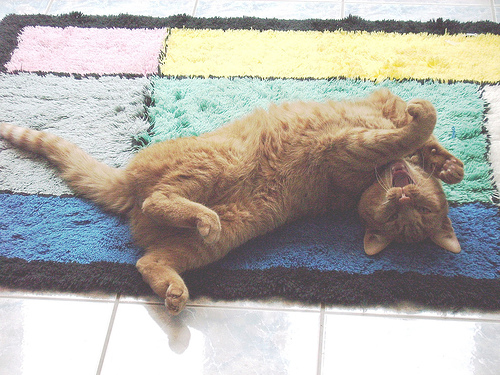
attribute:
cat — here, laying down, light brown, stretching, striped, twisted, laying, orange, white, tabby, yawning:
[0, 91, 460, 320]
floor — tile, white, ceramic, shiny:
[0, 2, 496, 371]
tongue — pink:
[389, 173, 411, 185]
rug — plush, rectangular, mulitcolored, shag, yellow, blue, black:
[3, 13, 500, 310]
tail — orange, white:
[4, 121, 126, 215]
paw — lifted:
[403, 98, 438, 134]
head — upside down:
[351, 161, 460, 262]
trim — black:
[0, 11, 499, 309]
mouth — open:
[388, 162, 410, 191]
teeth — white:
[392, 167, 406, 177]